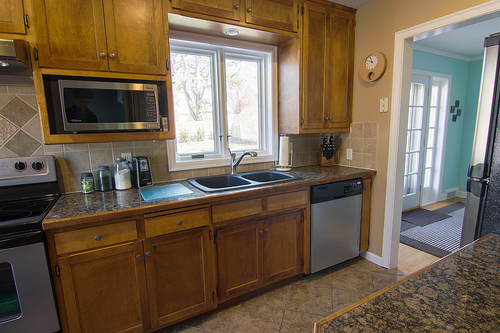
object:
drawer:
[144, 207, 210, 237]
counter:
[43, 163, 377, 333]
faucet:
[231, 150, 257, 175]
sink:
[195, 176, 251, 188]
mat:
[399, 202, 466, 259]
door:
[401, 67, 452, 211]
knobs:
[15, 162, 25, 170]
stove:
[0, 155, 65, 333]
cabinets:
[215, 206, 306, 298]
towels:
[279, 137, 289, 165]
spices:
[99, 177, 112, 191]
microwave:
[43, 75, 169, 135]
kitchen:
[0, 0, 499, 333]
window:
[168, 29, 279, 172]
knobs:
[110, 52, 116, 58]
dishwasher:
[311, 179, 362, 276]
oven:
[0, 242, 61, 333]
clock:
[365, 54, 378, 70]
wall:
[352, 0, 394, 123]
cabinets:
[31, 0, 169, 73]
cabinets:
[302, 1, 350, 127]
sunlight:
[168, 49, 222, 162]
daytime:
[0, 0, 499, 333]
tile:
[0, 94, 40, 130]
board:
[139, 183, 193, 201]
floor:
[156, 240, 443, 333]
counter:
[317, 229, 499, 332]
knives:
[323, 135, 328, 145]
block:
[318, 147, 333, 166]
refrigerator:
[456, 30, 499, 246]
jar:
[114, 157, 133, 190]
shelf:
[32, 68, 175, 146]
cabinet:
[246, 0, 296, 31]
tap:
[251, 152, 257, 157]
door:
[382, 0, 500, 271]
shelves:
[167, 0, 296, 46]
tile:
[284, 283, 332, 317]